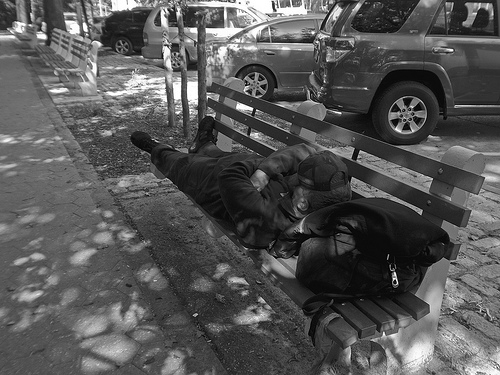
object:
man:
[129, 112, 360, 248]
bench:
[144, 73, 490, 373]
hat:
[291, 149, 352, 192]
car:
[308, 0, 500, 145]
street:
[0, 18, 500, 369]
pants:
[149, 140, 263, 221]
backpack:
[294, 205, 431, 303]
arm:
[259, 143, 315, 175]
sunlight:
[80, 303, 154, 361]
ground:
[0, 36, 500, 366]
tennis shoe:
[130, 130, 167, 156]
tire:
[368, 79, 444, 146]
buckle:
[386, 258, 402, 290]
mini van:
[137, 2, 276, 72]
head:
[287, 161, 353, 220]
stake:
[167, 29, 180, 45]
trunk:
[156, 2, 177, 131]